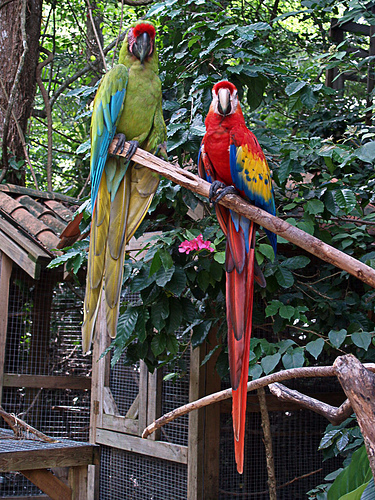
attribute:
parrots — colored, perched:
[90, 12, 277, 478]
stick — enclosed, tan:
[97, 131, 373, 314]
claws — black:
[104, 134, 240, 207]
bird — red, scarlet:
[192, 66, 274, 481]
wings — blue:
[211, 125, 284, 250]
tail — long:
[204, 225, 262, 483]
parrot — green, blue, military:
[62, 12, 165, 381]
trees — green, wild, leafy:
[0, 1, 375, 379]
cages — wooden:
[3, 184, 363, 496]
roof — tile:
[2, 188, 147, 284]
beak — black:
[130, 32, 158, 68]